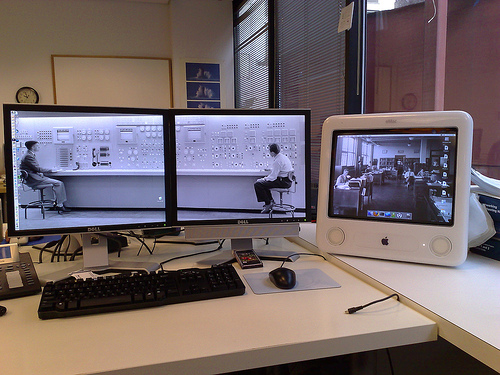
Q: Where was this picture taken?
A: Office.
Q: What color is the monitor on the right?
A: White.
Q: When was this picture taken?
A: Daytime.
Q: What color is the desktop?
A: White.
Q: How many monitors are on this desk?
A: Three.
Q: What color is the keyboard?
A: Black.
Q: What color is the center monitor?
A: Black.